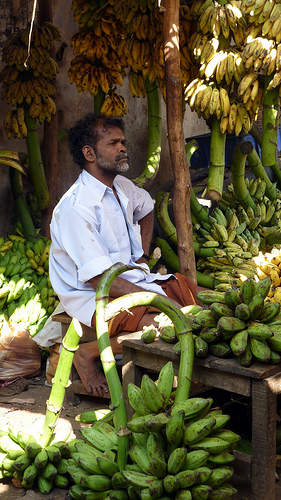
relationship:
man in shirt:
[48, 113, 183, 397] [63, 186, 135, 263]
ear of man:
[81, 144, 97, 162] [53, 110, 152, 273]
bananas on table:
[194, 209, 280, 304] [116, 329, 280, 499]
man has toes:
[48, 113, 183, 397] [87, 376, 119, 396]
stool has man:
[53, 308, 136, 379] [48, 113, 183, 397]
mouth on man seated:
[106, 148, 138, 168] [40, 290, 190, 386]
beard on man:
[98, 155, 134, 177] [45, 105, 185, 395]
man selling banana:
[47, 111, 201, 335] [213, 221, 228, 241]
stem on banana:
[69, 264, 209, 398] [0, 378, 232, 492]